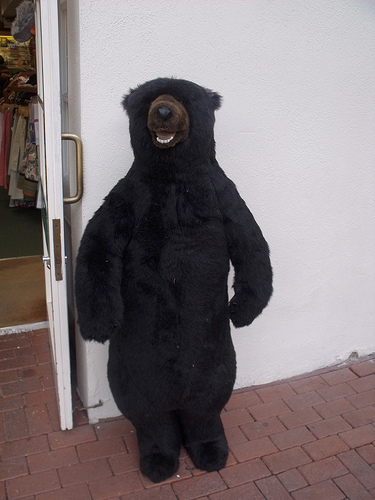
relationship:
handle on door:
[53, 125, 106, 212] [29, 6, 91, 433]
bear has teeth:
[59, 70, 287, 484] [145, 121, 203, 155]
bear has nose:
[59, 70, 287, 484] [152, 99, 186, 124]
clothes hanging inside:
[9, 16, 52, 208] [3, 1, 54, 323]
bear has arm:
[59, 70, 287, 484] [71, 188, 135, 347]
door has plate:
[29, 6, 91, 433] [45, 216, 73, 284]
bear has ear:
[59, 70, 287, 484] [188, 74, 229, 108]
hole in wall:
[338, 341, 368, 373] [256, 8, 370, 373]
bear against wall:
[59, 70, 287, 484] [256, 8, 370, 373]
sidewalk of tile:
[40, 378, 374, 491] [262, 445, 312, 475]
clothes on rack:
[9, 16, 52, 208] [0, 30, 38, 111]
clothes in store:
[9, 16, 52, 208] [3, 1, 54, 323]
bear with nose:
[59, 70, 287, 484] [152, 99, 186, 124]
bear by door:
[59, 70, 287, 484] [29, 6, 91, 433]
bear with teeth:
[59, 70, 287, 484] [145, 121, 203, 155]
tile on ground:
[259, 396, 357, 500] [40, 378, 374, 491]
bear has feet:
[59, 70, 287, 484] [126, 443, 243, 473]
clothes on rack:
[9, 16, 52, 208] [0, 65, 34, 79]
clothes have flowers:
[9, 16, 52, 208] [19, 140, 42, 185]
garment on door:
[13, 131, 72, 205] [29, 6, 91, 433]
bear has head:
[59, 70, 287, 484] [117, 77, 252, 173]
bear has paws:
[59, 70, 287, 484] [211, 281, 278, 336]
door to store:
[29, 6, 91, 433] [3, 1, 54, 323]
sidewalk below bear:
[40, 378, 374, 491] [59, 70, 287, 484]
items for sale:
[1, 4, 38, 206] [3, 11, 72, 392]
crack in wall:
[338, 341, 368, 373] [256, 8, 370, 373]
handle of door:
[53, 125, 106, 212] [29, 6, 91, 433]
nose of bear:
[152, 99, 186, 124] [59, 70, 287, 484]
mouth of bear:
[143, 99, 190, 146] [59, 70, 287, 484]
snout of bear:
[144, 97, 188, 145] [59, 70, 287, 484]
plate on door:
[45, 216, 73, 284] [29, 6, 91, 433]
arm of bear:
[71, 188, 135, 347] [59, 70, 287, 484]